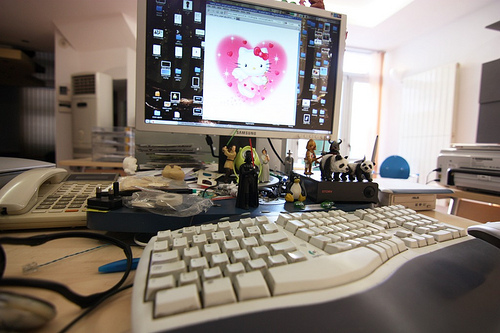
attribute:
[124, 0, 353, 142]
screen — pictured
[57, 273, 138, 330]
rope — pictured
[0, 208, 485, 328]
table — pictured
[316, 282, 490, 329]
table — pictured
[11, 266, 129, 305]
wire — Black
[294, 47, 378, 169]
window — pictured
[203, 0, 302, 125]
window — pictured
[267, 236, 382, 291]
button — White, Plain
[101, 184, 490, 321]
butt ons — White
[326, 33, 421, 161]
window — Natural 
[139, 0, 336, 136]
screen — pictured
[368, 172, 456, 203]
table — pictured